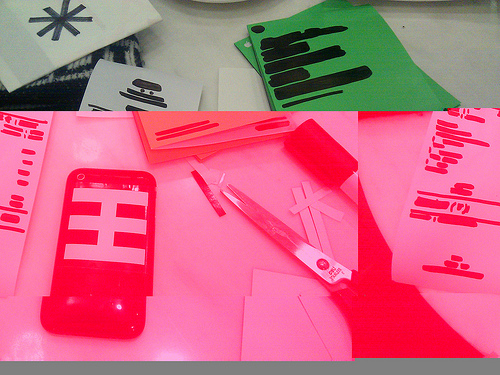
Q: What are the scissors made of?
A: Metal.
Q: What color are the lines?
A: Black.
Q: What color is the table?
A: White.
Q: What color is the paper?
A: Green and white.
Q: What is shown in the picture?
A: A desktop.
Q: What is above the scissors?
A: Paper.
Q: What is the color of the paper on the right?
A: Green.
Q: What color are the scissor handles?
A: Black.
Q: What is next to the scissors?
A: A cell phone.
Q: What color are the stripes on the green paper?
A: Black.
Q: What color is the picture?
A: Pink.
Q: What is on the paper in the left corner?
A: A star.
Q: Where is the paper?
A: On the table.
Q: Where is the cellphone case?
A: Not on the cell phone.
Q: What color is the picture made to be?
A: Pink.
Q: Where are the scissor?
A: Right side.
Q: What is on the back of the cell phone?
A: White lines.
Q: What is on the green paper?
A: Black marks.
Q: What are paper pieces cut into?
A: Strips.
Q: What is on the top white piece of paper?
A: A black marking.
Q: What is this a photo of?
A: Papers and objects.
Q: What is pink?
A: The lower half of the picture.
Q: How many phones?
A: One.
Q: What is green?
A: Paper.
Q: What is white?
A: Table.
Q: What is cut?
A: Paper.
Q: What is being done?
A: Crafts.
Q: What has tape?
A: Phone.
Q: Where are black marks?
A: On paper.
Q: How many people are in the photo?
A: None.